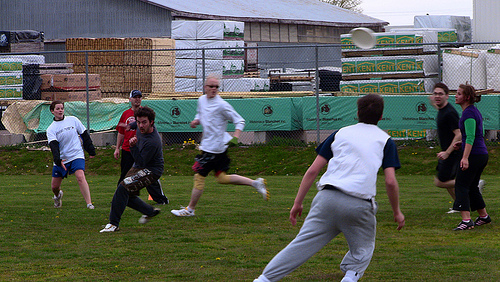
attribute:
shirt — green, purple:
[456, 105, 491, 156]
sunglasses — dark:
[209, 83, 219, 93]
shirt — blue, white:
[316, 120, 398, 201]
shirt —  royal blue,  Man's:
[45, 148, 92, 173]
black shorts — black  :
[190, 145, 226, 175]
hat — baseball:
[124, 82, 144, 99]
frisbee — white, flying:
[348, 28, 378, 50]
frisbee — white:
[338, 22, 385, 62]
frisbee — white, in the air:
[351, 27, 376, 49]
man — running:
[265, 77, 438, 251]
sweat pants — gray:
[239, 191, 392, 280]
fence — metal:
[28, 31, 493, 163]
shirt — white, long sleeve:
[193, 95, 243, 152]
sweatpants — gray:
[256, 187, 379, 280]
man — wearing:
[249, 91, 412, 278]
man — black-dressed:
[427, 81, 468, 227]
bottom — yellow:
[259, 178, 273, 204]